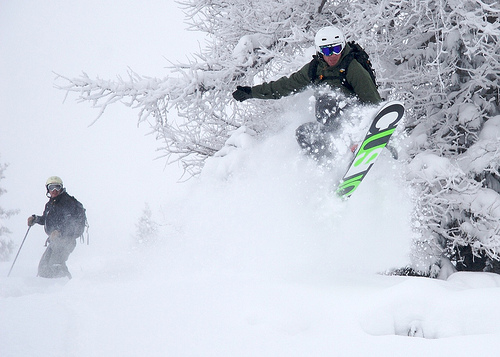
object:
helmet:
[314, 27, 345, 52]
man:
[232, 26, 402, 199]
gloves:
[232, 85, 255, 103]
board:
[334, 101, 406, 201]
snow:
[42, 20, 226, 178]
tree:
[58, 0, 498, 179]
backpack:
[334, 41, 377, 87]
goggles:
[319, 42, 345, 57]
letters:
[369, 104, 404, 134]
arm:
[252, 57, 317, 100]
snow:
[291, 106, 372, 193]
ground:
[82, 274, 487, 352]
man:
[8, 176, 90, 280]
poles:
[4, 225, 35, 278]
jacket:
[254, 55, 378, 109]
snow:
[10, 288, 500, 357]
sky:
[9, 12, 174, 66]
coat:
[39, 197, 85, 239]